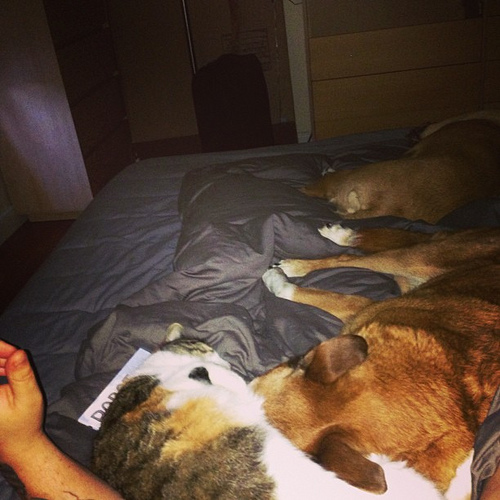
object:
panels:
[0, 0, 96, 215]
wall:
[282, 5, 318, 133]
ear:
[299, 334, 368, 382]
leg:
[303, 251, 420, 278]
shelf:
[0, 1, 135, 225]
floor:
[1, 219, 71, 313]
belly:
[236, 402, 324, 496]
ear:
[313, 440, 387, 493]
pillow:
[37, 291, 363, 471]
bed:
[2, 113, 499, 498]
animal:
[299, 112, 500, 224]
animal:
[247, 223, 500, 496]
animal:
[90, 322, 445, 499]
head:
[245, 332, 389, 495]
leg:
[349, 229, 424, 250]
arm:
[1, 425, 126, 500]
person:
[0, 343, 119, 497]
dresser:
[0, 0, 96, 227]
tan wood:
[300, 0, 499, 141]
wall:
[107, 50, 174, 97]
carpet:
[3, 219, 46, 254]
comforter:
[0, 124, 499, 500]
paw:
[317, 222, 357, 248]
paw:
[270, 258, 304, 277]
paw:
[262, 269, 287, 298]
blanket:
[0, 146, 499, 498]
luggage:
[189, 53, 275, 153]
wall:
[132, 101, 185, 143]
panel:
[304, 16, 500, 140]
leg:
[281, 282, 371, 321]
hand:
[0, 341, 46, 464]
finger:
[4, 348, 43, 406]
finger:
[0, 340, 17, 360]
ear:
[162, 323, 182, 343]